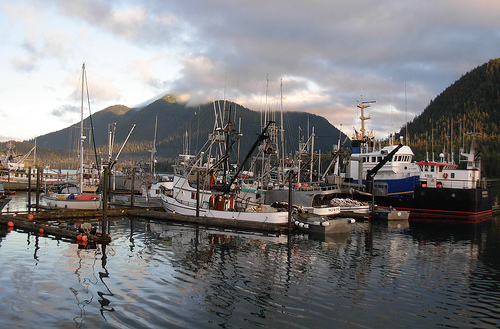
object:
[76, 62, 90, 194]
mast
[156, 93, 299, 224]
ship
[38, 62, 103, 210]
boat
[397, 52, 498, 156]
trees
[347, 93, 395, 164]
mast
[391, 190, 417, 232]
ground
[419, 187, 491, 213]
black paint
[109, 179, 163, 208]
boat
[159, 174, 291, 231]
boat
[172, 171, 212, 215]
cabin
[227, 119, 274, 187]
outrigger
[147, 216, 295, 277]
boat's reflection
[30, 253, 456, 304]
water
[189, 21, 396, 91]
clouds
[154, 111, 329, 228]
boats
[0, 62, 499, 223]
fleet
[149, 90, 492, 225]
boats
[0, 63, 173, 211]
boats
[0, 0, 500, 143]
cloudy skies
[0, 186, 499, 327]
water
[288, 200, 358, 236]
engine boat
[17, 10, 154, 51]
sky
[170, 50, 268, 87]
cloud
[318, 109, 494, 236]
ship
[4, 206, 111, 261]
bumper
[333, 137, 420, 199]
boat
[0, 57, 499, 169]
hill